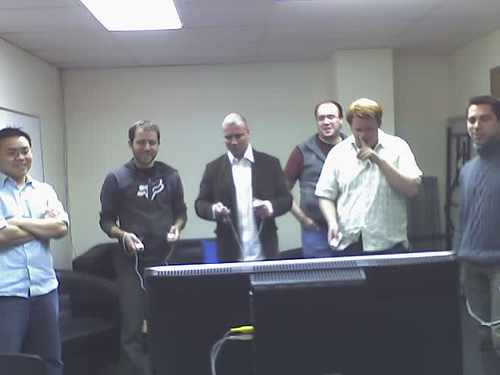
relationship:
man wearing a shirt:
[315, 97, 423, 259] [314, 128, 424, 251]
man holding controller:
[98, 121, 186, 373] [120, 224, 175, 290]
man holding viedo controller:
[192, 110, 293, 262] [216, 199, 270, 250]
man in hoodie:
[98, 121, 186, 373] [98, 159, 188, 257]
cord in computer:
[211, 324, 257, 374] [144, 252, 463, 372]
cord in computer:
[211, 324, 257, 374] [143, 236, 468, 368]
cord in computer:
[223, 324, 257, 343] [144, 252, 463, 372]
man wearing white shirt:
[192, 110, 293, 262] [225, 142, 266, 263]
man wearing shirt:
[98, 121, 186, 373] [94, 156, 190, 252]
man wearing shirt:
[0, 122, 75, 372] [0, 170, 71, 297]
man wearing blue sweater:
[445, 92, 499, 373] [450, 139, 499, 264]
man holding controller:
[98, 121, 186, 373] [107, 223, 185, 288]